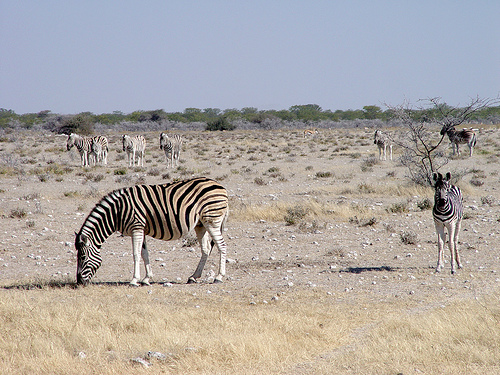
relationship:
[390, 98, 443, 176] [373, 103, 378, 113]
tree with no leaves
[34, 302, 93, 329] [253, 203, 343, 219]
patch of grass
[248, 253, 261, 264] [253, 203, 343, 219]
rock in grass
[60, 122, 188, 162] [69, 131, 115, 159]
group of zebras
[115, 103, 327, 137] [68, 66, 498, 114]
trees are on horizon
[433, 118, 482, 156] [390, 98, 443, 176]
zebra behind tree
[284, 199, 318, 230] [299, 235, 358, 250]
small bushes in dirt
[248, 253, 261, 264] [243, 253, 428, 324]
rock on ground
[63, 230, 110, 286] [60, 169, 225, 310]
head of zebra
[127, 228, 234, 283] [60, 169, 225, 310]
legs of a zebra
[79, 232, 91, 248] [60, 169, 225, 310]
ear of a zebra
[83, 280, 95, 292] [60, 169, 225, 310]
mouth of a zebra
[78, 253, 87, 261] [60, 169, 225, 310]
eye of a zebra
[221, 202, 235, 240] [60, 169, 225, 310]
tail of a zebra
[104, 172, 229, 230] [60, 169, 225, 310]
body of a zebra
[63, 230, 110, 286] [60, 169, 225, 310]
head of a zebra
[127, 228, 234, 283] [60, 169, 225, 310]
legs of zebra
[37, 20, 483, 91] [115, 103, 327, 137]
skies over trees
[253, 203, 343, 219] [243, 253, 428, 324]
grass covering ground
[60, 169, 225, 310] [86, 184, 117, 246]
zebra bending neck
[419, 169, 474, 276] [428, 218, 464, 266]
zebra has legs